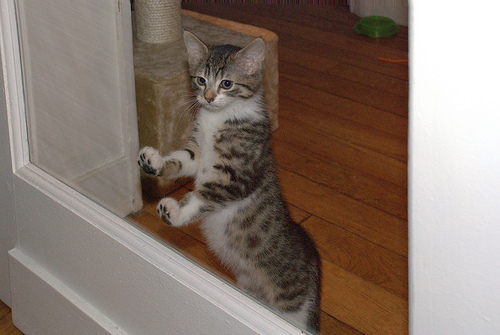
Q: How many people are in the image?
A: 0.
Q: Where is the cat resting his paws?
A: On the window.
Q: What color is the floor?
A: Brown.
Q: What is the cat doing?
A: Looking out the window.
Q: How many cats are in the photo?
A: 1.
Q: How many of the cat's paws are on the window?
A: 2.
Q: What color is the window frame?
A: White.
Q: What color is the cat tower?
A: Tan.